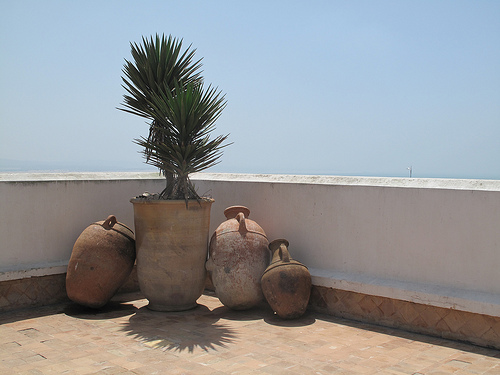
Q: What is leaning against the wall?
A: A large tan pot.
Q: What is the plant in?
A: A large pot.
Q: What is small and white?
A: Wall.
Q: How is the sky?
A: Bright and light blue.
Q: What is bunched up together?
A: Four pots.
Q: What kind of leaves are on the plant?
A: Green spikey leaves.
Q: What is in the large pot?
A: A plant.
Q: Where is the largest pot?
A: Between two other pots.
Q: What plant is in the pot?
A: Palm tree.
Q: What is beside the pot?
A: Water pots.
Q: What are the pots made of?
A: Clay.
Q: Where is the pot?
A: In the corner.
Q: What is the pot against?
A: A wall.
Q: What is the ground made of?
A: Tiles.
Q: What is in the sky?
A: Clouds.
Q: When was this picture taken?
A: This picture was taken on a sunny cloudless day.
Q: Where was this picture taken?
A: This picture was taken on a balcony.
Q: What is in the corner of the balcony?
A: A palm tree.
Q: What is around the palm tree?
A: Pots.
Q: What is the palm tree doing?
A: Casting a shadow.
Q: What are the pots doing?
A: Leaning against the palm tree.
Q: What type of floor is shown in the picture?
A: A tile floor.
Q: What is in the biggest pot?
A: A palm tree.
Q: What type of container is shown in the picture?
A: Clay pots.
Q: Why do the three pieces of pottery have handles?
A: Carry.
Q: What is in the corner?
A: Tree.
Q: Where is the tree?
A: Corner.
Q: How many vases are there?
A: Four.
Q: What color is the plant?
A: Green.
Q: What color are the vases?
A: Brown.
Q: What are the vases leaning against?
A: Wall.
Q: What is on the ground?
A: Bricks.